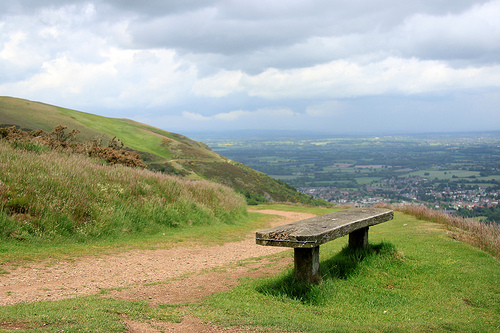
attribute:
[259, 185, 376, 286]
bench — old, worn out, wooden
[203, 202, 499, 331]
grass — green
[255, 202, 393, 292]
bench — stone, wooden, brown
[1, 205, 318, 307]
trail — heavily walked on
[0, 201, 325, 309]
road — dirt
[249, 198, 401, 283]
bench — wooden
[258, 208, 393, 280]
bench — wood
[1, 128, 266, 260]
grass — green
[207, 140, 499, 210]
town — small, farm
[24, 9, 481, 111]
clouds — white, large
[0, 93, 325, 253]
grass — long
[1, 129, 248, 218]
grass — dry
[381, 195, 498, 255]
grass — dry